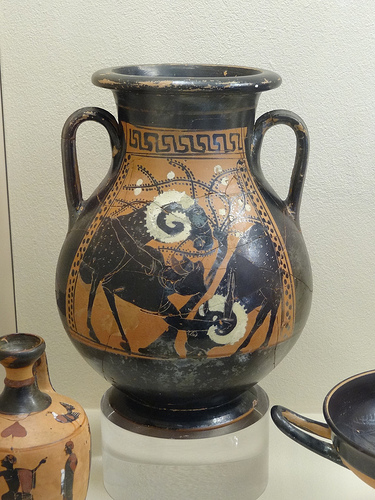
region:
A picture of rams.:
[63, 120, 294, 362]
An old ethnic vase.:
[53, 60, 316, 438]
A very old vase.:
[0, 332, 91, 499]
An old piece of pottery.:
[268, 369, 374, 492]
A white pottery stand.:
[99, 407, 270, 498]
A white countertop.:
[86, 409, 374, 498]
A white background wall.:
[0, 0, 374, 410]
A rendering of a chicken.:
[45, 399, 83, 431]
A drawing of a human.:
[0, 452, 48, 497]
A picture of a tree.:
[111, 156, 268, 359]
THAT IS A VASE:
[5, 319, 101, 487]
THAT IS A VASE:
[58, 60, 270, 385]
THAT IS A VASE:
[286, 392, 364, 464]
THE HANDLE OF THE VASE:
[60, 101, 115, 185]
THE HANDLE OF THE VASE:
[248, 98, 318, 200]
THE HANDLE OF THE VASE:
[266, 403, 321, 449]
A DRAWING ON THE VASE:
[58, 436, 74, 492]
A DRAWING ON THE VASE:
[3, 449, 29, 495]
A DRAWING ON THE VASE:
[148, 190, 211, 244]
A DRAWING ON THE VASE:
[44, 393, 88, 425]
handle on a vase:
[250, 106, 318, 205]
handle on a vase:
[264, 401, 347, 462]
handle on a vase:
[56, 94, 133, 218]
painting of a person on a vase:
[58, 432, 79, 498]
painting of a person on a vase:
[0, 447, 56, 498]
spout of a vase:
[0, 323, 62, 410]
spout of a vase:
[88, 40, 281, 121]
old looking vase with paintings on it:
[0, 311, 112, 498]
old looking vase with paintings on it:
[40, 49, 332, 443]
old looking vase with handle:
[261, 351, 373, 496]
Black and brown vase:
[50, 56, 322, 447]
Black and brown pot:
[269, 360, 374, 488]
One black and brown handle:
[52, 103, 131, 221]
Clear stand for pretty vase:
[89, 406, 281, 499]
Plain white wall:
[1, 1, 374, 416]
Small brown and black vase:
[0, 328, 99, 499]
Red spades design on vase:
[0, 414, 36, 445]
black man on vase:
[54, 440, 94, 499]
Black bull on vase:
[76, 209, 217, 361]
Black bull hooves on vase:
[84, 323, 142, 357]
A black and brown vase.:
[52, 65, 313, 441]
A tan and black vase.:
[0, 331, 92, 498]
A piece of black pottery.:
[271, 364, 374, 488]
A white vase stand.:
[100, 407, 269, 499]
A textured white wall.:
[1, 1, 373, 415]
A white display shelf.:
[82, 407, 373, 499]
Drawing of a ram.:
[80, 189, 213, 357]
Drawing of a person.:
[60, 439, 79, 499]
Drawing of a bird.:
[44, 398, 85, 430]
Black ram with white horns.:
[184, 222, 282, 359]